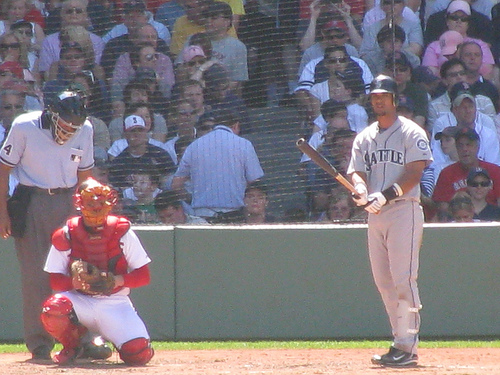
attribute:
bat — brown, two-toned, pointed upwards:
[294, 137, 356, 195]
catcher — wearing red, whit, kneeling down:
[40, 178, 156, 366]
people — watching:
[0, 2, 500, 222]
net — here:
[0, 4, 500, 222]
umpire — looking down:
[2, 92, 96, 359]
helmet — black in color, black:
[369, 75, 400, 107]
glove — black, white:
[365, 186, 401, 210]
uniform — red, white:
[40, 216, 155, 364]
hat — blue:
[452, 129, 478, 140]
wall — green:
[0, 223, 500, 337]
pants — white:
[54, 289, 150, 351]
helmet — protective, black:
[54, 91, 86, 128]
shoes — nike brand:
[369, 346, 418, 366]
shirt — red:
[431, 158, 498, 203]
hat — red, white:
[121, 115, 147, 132]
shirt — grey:
[3, 111, 94, 186]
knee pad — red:
[117, 336, 154, 364]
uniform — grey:
[345, 117, 433, 355]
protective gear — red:
[67, 216, 133, 295]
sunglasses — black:
[468, 181, 489, 187]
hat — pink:
[445, 0, 474, 14]